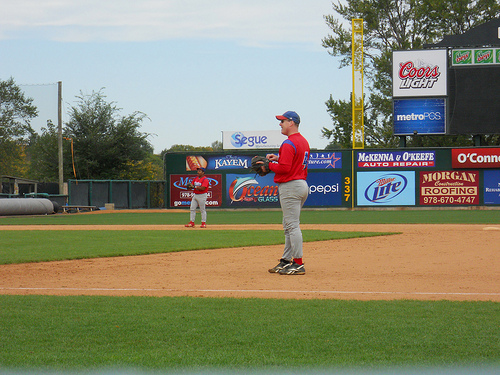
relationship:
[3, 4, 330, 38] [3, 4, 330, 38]
clouds covered with clouds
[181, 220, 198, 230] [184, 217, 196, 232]
shoe on foot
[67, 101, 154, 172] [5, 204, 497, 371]
trees beside field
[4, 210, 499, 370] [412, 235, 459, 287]
floor covered with soil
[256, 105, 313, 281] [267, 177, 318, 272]
fielder has grey pants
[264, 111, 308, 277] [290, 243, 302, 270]
fielder has socks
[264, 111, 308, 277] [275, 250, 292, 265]
fielder has socks